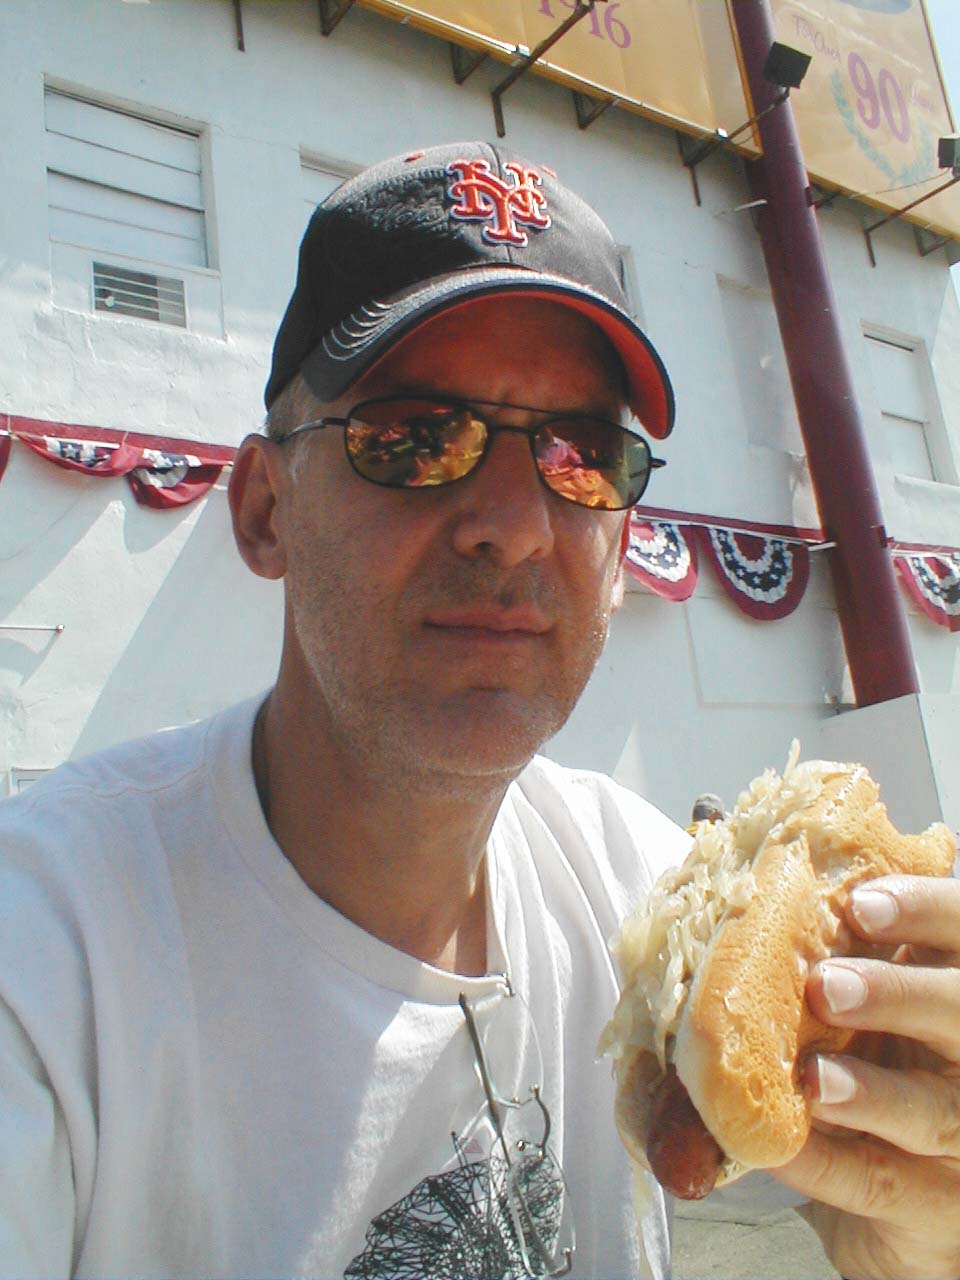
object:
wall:
[0, 0, 959, 1221]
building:
[6, 8, 956, 825]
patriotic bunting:
[0, 404, 960, 634]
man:
[4, 148, 957, 1280]